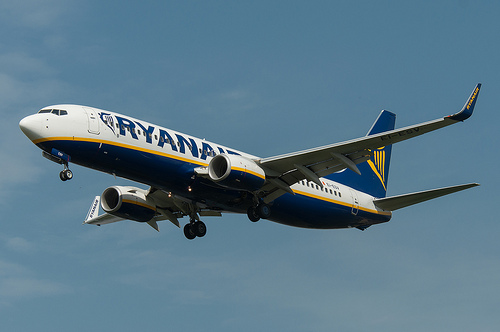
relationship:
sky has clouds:
[60, 237, 431, 317] [4, 227, 76, 318]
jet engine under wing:
[209, 150, 266, 192] [253, 81, 488, 193]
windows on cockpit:
[27, 105, 65, 116] [25, 90, 90, 148]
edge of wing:
[259, 113, 446, 165] [197, 80, 482, 197]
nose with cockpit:
[18, 106, 57, 129] [40, 106, 67, 114]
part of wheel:
[200, 227, 206, 237] [188, 220, 207, 237]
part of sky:
[234, 248, 368, 324] [0, 0, 497, 329]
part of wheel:
[200, 224, 205, 234] [238, 196, 280, 226]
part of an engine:
[218, 167, 232, 180] [203, 152, 247, 185]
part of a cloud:
[2, 280, 62, 304] [7, 16, 124, 328]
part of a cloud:
[4, 162, 38, 184] [5, 0, 73, 330]